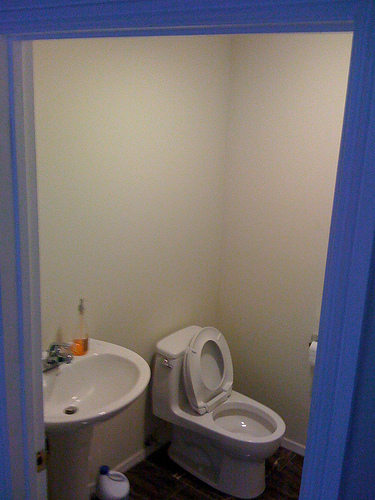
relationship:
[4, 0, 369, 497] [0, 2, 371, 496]
wall has door frame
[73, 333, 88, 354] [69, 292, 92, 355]
soap in container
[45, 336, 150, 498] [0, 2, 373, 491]
sink in bathroom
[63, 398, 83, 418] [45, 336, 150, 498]
drain in sink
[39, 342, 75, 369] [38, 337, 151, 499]
faucet in sink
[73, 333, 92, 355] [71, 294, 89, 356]
soap in container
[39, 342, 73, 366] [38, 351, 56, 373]
faucet has handle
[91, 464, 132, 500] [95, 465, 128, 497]
bleach of bleach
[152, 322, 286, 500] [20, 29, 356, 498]
porcelain toilet in bathroom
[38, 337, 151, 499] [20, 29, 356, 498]
sink in bathroom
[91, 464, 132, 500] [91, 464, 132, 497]
bleach of bleach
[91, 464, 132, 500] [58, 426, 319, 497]
bleach on floor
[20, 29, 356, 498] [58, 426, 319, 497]
bathroom has floor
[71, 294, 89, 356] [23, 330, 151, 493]
container on sink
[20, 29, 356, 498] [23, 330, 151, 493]
bathroom has sink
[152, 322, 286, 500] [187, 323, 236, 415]
porcelain toilet has seat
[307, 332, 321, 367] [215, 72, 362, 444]
paper hanging from wall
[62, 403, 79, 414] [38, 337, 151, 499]
drain to sink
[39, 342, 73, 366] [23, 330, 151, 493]
faucet to sink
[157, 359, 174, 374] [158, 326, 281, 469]
handle to toilet